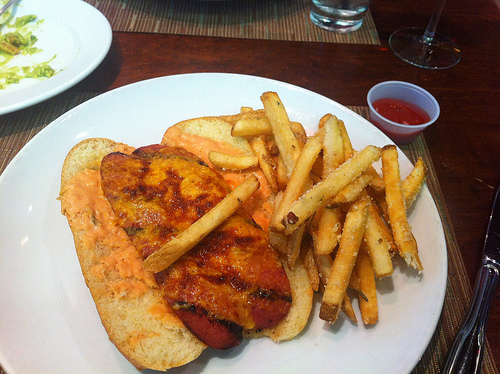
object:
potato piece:
[270, 251, 311, 343]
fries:
[144, 91, 427, 324]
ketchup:
[366, 81, 440, 144]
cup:
[366, 79, 442, 144]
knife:
[441, 181, 500, 374]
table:
[0, 0, 497, 371]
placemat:
[83, 0, 380, 47]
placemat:
[0, 71, 444, 373]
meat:
[99, 142, 291, 346]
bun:
[59, 92, 427, 372]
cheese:
[99, 143, 294, 349]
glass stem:
[421, 1, 447, 41]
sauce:
[163, 193, 222, 291]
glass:
[308, 0, 365, 34]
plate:
[0, 0, 113, 116]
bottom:
[387, 28, 461, 70]